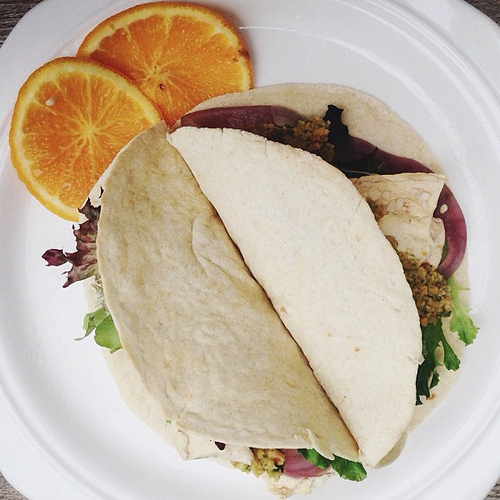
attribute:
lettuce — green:
[77, 310, 120, 352]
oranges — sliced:
[9, 2, 251, 224]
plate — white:
[1, 11, 497, 498]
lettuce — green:
[58, 292, 139, 380]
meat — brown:
[382, 230, 454, 330]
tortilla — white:
[80, 124, 366, 487]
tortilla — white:
[168, 82, 448, 460]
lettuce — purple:
[50, 200, 107, 348]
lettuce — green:
[409, 270, 476, 400]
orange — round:
[10, 55, 167, 222]